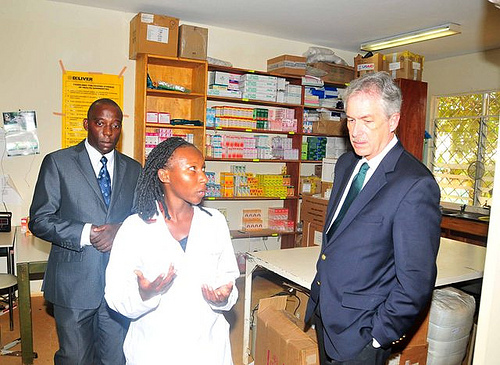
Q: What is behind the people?
A: Wood shelves.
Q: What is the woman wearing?
A: Lab coat.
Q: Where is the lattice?
A: On window.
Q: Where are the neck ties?
A: The men.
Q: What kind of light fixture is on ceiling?
A: Fluorescent.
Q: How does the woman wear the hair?
A: Braids.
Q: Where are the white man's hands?
A: In pockets.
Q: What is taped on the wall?
A: Yellow poster.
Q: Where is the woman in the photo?
A: In middle.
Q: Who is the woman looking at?
A: The Caucasian man.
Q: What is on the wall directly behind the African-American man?
A: A yellow sign.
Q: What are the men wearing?
A: Suits.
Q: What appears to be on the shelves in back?
A: Supplies.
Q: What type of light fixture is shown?
A: Fluorescent.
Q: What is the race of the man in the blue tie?
A: African-American.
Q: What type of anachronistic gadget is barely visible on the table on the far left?
A: Transistor radio.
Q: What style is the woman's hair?
A: Braids.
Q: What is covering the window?
A: Fence.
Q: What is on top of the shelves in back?
A: Boxes.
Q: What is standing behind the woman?
A: The man.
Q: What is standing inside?
A: The people.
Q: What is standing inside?
A: Three people.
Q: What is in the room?
A: Three people.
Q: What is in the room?
A: The people.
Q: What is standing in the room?
A: The People.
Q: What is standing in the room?
A: Three people.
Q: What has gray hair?
A: The man.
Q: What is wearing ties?
A: Two men.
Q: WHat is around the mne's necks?
A: Ties.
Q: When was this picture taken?
A: Daytime.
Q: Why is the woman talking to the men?
A: She is explaining.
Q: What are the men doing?
A: Listening.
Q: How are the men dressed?
A: In suits.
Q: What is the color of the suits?
A: Grey.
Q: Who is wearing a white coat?
A: The woman.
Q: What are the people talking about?
A: A serious subject.